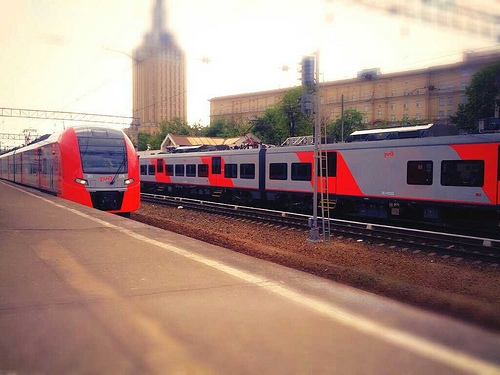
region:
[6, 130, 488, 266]
trains on the track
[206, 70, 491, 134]
building behind the train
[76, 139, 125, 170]
window on the train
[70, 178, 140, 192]
lights on the train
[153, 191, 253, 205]
wheels on the train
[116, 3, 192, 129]
building behind the train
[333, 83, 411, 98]
windows on the building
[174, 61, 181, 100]
windows on the building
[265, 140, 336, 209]
A grey and orange car train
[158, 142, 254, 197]
A grey and orange car train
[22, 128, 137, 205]
A grey and orange car train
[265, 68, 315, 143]
A green tall tree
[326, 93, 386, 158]
A green tall tree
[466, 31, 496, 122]
A green tall tree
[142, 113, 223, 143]
A green tall tree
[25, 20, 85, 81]
A clear cloud sky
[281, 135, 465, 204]
this is the train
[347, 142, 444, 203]
the train is long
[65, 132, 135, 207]
this is the front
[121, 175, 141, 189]
this is the light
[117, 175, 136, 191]
the light is on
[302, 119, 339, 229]
this is a pole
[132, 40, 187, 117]
this is a building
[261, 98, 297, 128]
these are the trees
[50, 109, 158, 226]
the front of a red and gray train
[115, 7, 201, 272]
tall building in the background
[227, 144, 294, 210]
the connecting section between train cars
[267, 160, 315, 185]
windows on a train car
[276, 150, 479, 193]
the side of a train car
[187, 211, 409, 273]
gravel on train tracks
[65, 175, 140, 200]
headlights on a train car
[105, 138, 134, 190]
windsheild wiper on a train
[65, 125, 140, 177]
windshield on the front of the train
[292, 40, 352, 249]
a long pole between train tracks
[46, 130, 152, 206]
this is a train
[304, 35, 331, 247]
this is a pole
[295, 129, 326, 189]
the pole is white in color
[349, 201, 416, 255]
this is a railway line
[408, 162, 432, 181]
this is the window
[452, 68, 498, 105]
this is a tree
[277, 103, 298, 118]
the leaves are green in color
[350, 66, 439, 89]
this is a building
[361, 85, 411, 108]
this is the wall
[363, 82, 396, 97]
the wall is brown in color